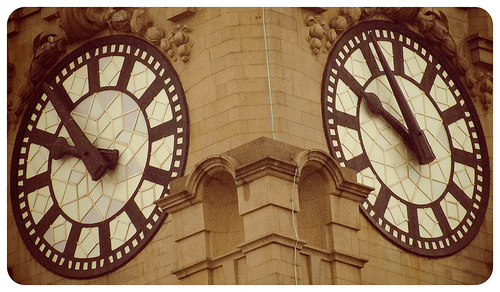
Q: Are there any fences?
A: No, there are no fences.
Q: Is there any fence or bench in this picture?
A: No, there are no fences or benches.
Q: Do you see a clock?
A: Yes, there is a clock.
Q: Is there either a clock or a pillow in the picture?
A: Yes, there is a clock.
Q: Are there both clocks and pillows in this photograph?
A: No, there is a clock but no pillows.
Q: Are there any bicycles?
A: No, there are no bicycles.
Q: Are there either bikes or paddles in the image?
A: No, there are no bikes or paddles.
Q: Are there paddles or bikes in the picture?
A: No, there are no bikes or paddles.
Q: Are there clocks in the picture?
A: Yes, there is a clock.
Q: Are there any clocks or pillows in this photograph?
A: Yes, there is a clock.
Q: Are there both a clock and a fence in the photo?
A: No, there is a clock but no fences.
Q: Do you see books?
A: No, there are no books.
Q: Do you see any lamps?
A: No, there are no lamps.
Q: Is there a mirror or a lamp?
A: No, there are no lamps or mirrors.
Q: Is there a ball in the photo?
A: No, there are no balls.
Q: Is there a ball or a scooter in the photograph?
A: No, there are no balls or scooters.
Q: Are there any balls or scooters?
A: No, there are no balls or scooters.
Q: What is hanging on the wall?
A: The cable is hanging on the wall.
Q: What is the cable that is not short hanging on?
A: The cable is hanging on the wall.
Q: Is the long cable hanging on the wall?
A: Yes, the cable is hanging on the wall.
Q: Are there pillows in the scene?
A: No, there are no pillows.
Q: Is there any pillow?
A: No, there are no pillows.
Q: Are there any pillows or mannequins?
A: No, there are no pillows or mannequins.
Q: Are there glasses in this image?
A: No, there are no glasses.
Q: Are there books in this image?
A: No, there are no books.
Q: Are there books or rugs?
A: No, there are no books or rugs.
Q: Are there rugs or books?
A: No, there are no books or rugs.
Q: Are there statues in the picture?
A: No, there are no statues.